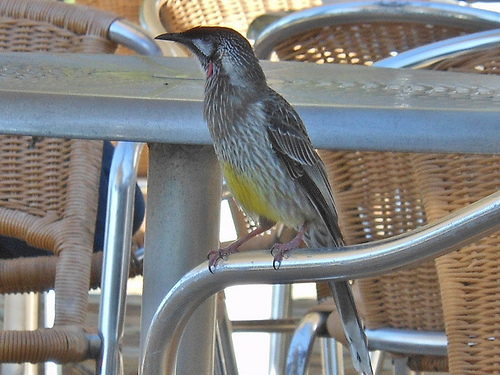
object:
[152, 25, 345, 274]
bird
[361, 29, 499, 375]
chair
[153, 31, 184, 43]
beak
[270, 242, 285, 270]
foot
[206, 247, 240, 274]
foot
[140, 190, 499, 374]
metal arm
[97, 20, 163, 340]
metal arm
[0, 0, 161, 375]
chair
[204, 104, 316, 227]
belly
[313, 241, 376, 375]
tailfeathers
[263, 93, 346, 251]
side wing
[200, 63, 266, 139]
neck feathers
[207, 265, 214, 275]
claw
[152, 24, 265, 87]
head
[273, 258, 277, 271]
claws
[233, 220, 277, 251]
leg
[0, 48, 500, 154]
table